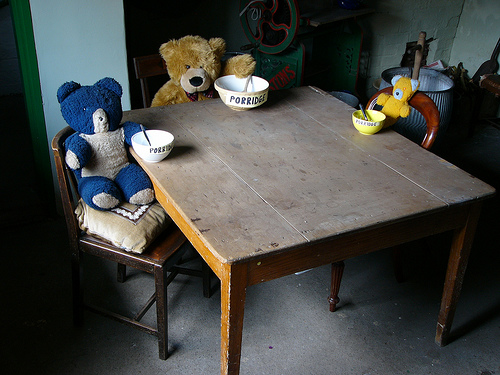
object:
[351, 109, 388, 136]
bowl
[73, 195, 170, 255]
throw pillow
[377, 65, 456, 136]
garbage can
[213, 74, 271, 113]
bowl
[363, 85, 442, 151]
chair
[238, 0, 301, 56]
wheel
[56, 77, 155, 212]
bear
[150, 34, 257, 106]
teddy bear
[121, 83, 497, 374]
dining table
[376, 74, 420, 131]
teddy bear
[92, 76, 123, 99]
ear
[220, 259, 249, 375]
leg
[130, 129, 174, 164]
bowl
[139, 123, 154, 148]
eating utensil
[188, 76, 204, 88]
nose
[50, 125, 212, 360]
chair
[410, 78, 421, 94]
ear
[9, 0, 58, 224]
door frame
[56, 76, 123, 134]
head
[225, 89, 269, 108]
label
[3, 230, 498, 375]
flooring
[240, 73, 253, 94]
spoon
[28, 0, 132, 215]
wall